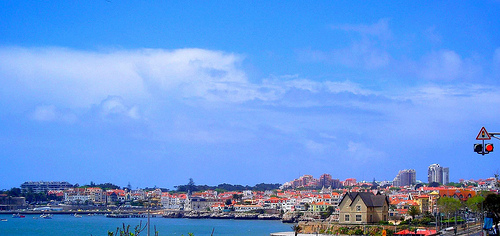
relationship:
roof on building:
[314, 195, 327, 203] [309, 196, 331, 216]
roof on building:
[103, 187, 119, 194] [104, 187, 122, 204]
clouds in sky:
[0, 45, 499, 155] [0, 2, 495, 187]